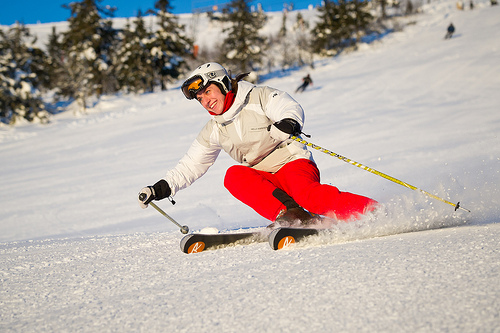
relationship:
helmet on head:
[182, 57, 236, 92] [183, 55, 234, 113]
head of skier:
[183, 55, 234, 113] [129, 54, 399, 255]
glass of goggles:
[184, 76, 203, 88] [179, 78, 207, 93]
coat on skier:
[146, 86, 302, 193] [129, 54, 399, 255]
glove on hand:
[141, 178, 178, 206] [138, 176, 174, 208]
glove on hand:
[264, 115, 306, 144] [261, 115, 304, 141]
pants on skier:
[219, 164, 375, 226] [129, 54, 399, 255]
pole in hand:
[144, 203, 192, 232] [138, 176, 174, 208]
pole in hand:
[296, 135, 462, 209] [261, 115, 304, 141]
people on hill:
[293, 71, 318, 94] [336, 44, 498, 173]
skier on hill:
[442, 20, 457, 43] [336, 44, 498, 173]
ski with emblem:
[180, 232, 265, 256] [188, 240, 210, 252]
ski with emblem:
[266, 225, 326, 247] [277, 234, 298, 251]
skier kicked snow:
[129, 54, 399, 255] [335, 201, 497, 242]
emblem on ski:
[188, 240, 210, 252] [180, 232, 265, 256]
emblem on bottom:
[277, 234, 298, 251] [270, 229, 367, 251]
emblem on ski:
[277, 234, 298, 251] [266, 225, 326, 247]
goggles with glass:
[179, 78, 207, 93] [181, 78, 204, 90]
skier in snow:
[129, 54, 399, 255] [335, 201, 497, 242]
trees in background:
[8, 0, 384, 59] [8, 1, 499, 105]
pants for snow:
[219, 164, 375, 226] [335, 201, 497, 242]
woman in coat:
[129, 54, 399, 255] [146, 86, 302, 193]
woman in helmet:
[129, 54, 399, 255] [182, 57, 236, 92]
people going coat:
[298, 67, 327, 89] [158, 79, 317, 197]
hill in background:
[336, 44, 498, 173] [8, 1, 499, 105]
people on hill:
[298, 67, 327, 89] [336, 44, 498, 173]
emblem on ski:
[274, 233, 301, 257] [266, 225, 326, 247]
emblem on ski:
[183, 239, 220, 262] [180, 232, 265, 256]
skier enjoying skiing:
[129, 54, 399, 255] [104, 60, 498, 223]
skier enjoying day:
[129, 54, 399, 255] [6, 7, 498, 237]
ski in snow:
[180, 232, 265, 256] [335, 201, 497, 242]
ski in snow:
[266, 225, 326, 247] [335, 201, 497, 242]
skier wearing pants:
[129, 54, 399, 255] [219, 164, 375, 226]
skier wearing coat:
[129, 54, 399, 255] [158, 79, 317, 197]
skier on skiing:
[129, 54, 399, 255] [104, 58, 497, 261]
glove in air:
[141, 178, 178, 206] [5, 0, 497, 305]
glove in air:
[264, 115, 306, 144] [5, 0, 497, 305]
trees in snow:
[8, 0, 384, 59] [335, 201, 497, 242]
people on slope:
[298, 67, 327, 89] [305, 49, 499, 178]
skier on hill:
[129, 54, 399, 255] [336, 44, 498, 173]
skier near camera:
[129, 54, 399, 255] [208, 293, 304, 332]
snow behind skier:
[335, 201, 497, 242] [129, 54, 399, 255]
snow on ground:
[335, 201, 497, 242] [0, 240, 440, 321]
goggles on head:
[179, 78, 207, 93] [183, 55, 234, 113]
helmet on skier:
[182, 57, 236, 92] [129, 54, 399, 255]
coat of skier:
[146, 86, 302, 193] [129, 54, 399, 255]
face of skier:
[197, 83, 228, 115] [129, 54, 399, 255]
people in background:
[293, 71, 318, 94] [8, 1, 499, 105]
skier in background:
[442, 20, 457, 43] [8, 1, 499, 105]